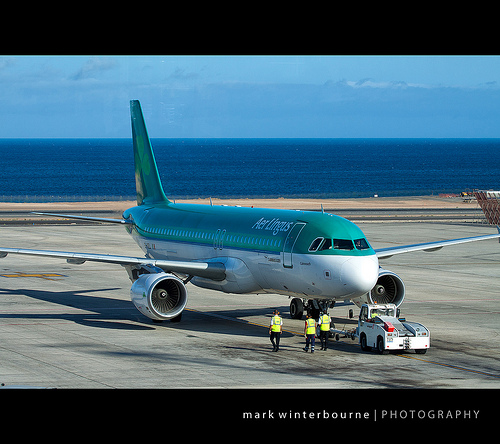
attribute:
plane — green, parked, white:
[122, 100, 418, 316]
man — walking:
[265, 313, 285, 340]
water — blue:
[2, 132, 497, 190]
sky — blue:
[0, 50, 497, 136]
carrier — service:
[356, 302, 437, 357]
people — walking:
[267, 312, 336, 353]